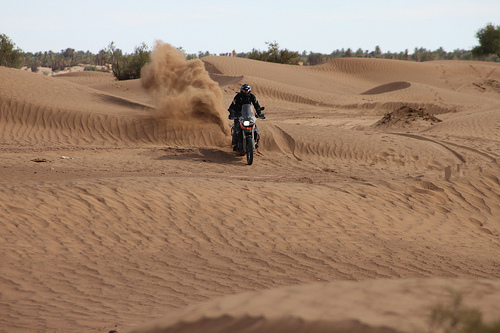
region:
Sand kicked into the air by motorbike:
[162, 67, 197, 93]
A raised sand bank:
[20, 111, 65, 136]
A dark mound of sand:
[371, 102, 438, 123]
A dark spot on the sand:
[30, 156, 45, 161]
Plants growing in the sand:
[120, 60, 132, 71]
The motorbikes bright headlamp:
[240, 120, 250, 125]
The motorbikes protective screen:
[241, 102, 251, 113]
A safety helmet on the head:
[237, 80, 247, 91]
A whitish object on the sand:
[56, 152, 66, 157]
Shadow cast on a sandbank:
[380, 87, 406, 90]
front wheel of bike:
[227, 125, 269, 172]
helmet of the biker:
[237, 73, 255, 99]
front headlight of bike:
[239, 113, 254, 130]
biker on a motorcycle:
[225, 71, 292, 176]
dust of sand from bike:
[164, 51, 235, 133]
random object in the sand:
[47, 138, 81, 169]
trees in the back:
[248, 39, 348, 64]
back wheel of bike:
[222, 125, 246, 153]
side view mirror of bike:
[254, 113, 269, 125]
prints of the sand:
[352, 126, 427, 204]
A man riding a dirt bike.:
[214, 77, 272, 182]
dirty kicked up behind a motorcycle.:
[129, 30, 237, 145]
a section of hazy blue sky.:
[1, 0, 498, 55]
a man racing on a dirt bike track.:
[224, 66, 272, 165]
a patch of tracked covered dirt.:
[0, 91, 414, 180]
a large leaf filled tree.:
[464, 18, 498, 62]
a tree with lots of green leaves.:
[1, 25, 36, 67]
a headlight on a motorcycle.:
[240, 110, 257, 130]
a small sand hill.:
[361, 66, 469, 97]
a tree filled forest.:
[0, 20, 498, 84]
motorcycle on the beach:
[222, 78, 272, 166]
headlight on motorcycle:
[240, 118, 254, 130]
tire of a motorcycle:
[239, 133, 261, 165]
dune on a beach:
[356, 78, 447, 103]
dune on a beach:
[313, 51, 423, 78]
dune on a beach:
[102, 257, 498, 332]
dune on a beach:
[17, 96, 367, 170]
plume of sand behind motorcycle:
[131, 34, 231, 132]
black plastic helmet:
[237, 80, 252, 98]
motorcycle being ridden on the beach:
[216, 80, 270, 170]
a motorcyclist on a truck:
[222, 65, 277, 171]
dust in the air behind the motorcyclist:
[131, 28, 238, 160]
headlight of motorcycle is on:
[228, 103, 270, 166]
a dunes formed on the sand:
[258, 38, 493, 115]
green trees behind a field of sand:
[3, 19, 499, 75]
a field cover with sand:
[6, 60, 498, 332]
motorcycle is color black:
[222, 105, 270, 169]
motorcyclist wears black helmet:
[220, 71, 268, 128]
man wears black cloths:
[216, 73, 273, 137]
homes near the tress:
[9, 43, 123, 85]